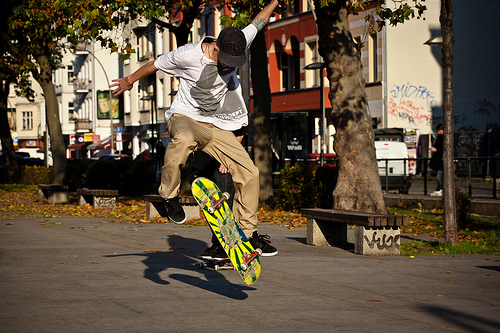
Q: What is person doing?
A: Skateboarding.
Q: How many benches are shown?
A: 4.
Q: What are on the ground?
A: Leaves.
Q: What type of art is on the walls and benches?
A: Graffiti.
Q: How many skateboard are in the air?
A: 1.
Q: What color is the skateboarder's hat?
A: Black.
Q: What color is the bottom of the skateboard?
A: Blue and yellow.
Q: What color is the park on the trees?
A: Grey.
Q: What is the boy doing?
A: Riding a skateboard.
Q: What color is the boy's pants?
A: Tan.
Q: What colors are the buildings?
A: Red and white.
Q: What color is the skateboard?
A: Yellow and blue.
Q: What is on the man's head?
A: A ball cap.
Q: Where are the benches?
A: Along the sidewalk.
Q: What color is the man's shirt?
A: White.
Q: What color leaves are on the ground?
A: Yellow.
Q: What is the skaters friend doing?
A: Standing around watching.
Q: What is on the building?
A: Graffiti.